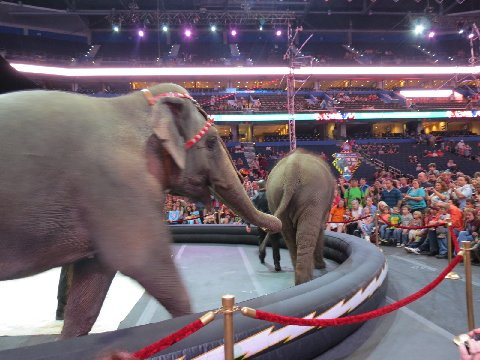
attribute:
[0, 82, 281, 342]
elephant — gray, walking, grey, large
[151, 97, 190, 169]
ear — floppy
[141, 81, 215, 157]
harness — red, white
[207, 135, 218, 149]
eye — open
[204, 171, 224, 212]
mouth — open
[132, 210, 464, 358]
ropes — red, velvet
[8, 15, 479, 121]
lights — bright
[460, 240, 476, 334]
pole — gold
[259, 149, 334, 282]
elephant — walking, large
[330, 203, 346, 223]
shirt — orange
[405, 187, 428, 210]
shirt — blue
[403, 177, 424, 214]
woman — standing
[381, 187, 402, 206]
shirt — blue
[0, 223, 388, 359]
circus ring — inflatable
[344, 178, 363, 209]
man — standing